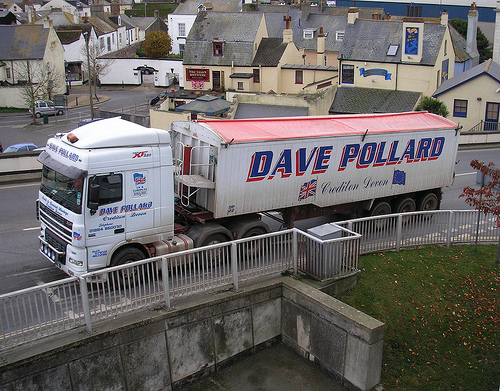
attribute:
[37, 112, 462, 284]
truck — white, large, red white, blue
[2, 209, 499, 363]
railing — white, metal, grey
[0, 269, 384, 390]
wall — white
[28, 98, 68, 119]
vehicle — gray, grey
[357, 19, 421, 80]
signs — blue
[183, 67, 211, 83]
sign — red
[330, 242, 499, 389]
grass — green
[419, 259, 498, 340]
leaves — brown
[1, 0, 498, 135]
group of buildings — large, together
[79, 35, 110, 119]
tree — dormant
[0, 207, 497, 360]
fence — white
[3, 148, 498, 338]
road — gray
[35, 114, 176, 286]
cab — white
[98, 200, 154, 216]
lettering — blue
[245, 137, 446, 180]
lettering — red, blue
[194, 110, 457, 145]
top — plastic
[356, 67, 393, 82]
banner — blue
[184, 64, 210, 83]
banner — red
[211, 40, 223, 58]
window — red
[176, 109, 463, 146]
roof — red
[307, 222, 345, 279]
box — grey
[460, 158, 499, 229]
leaves — brown